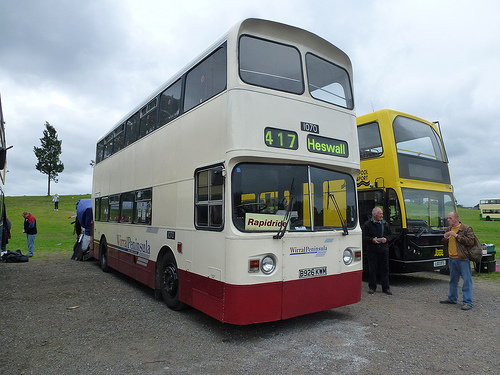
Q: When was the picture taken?
A: Daytime.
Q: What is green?
A: Grass.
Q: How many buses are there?
A: Two.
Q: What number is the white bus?
A: 417.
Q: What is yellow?
A: Bus on right.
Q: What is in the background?
A: A tree.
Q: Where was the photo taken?
A: At rest area.